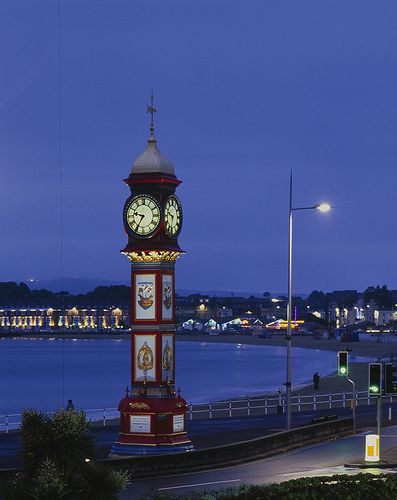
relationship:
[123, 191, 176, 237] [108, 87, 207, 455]
clock on tower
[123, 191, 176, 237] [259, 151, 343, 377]
clock near light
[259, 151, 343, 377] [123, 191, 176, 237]
light near clock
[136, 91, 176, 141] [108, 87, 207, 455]
weather vane on top of a tower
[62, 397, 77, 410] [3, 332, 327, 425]
person standing water